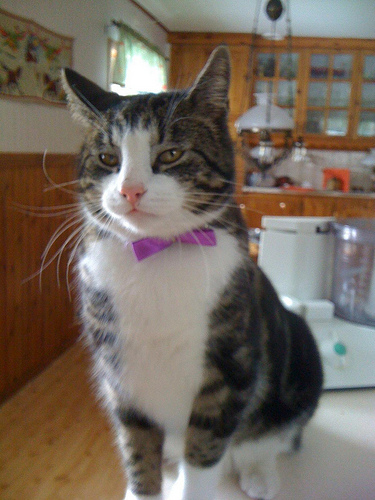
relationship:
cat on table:
[18, 43, 325, 499] [2, 143, 260, 498]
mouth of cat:
[105, 205, 164, 224] [29, 54, 362, 494]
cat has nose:
[18, 43, 325, 499] [116, 183, 147, 203]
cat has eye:
[18, 43, 325, 499] [155, 141, 190, 171]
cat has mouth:
[18, 43, 325, 499] [118, 200, 161, 220]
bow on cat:
[131, 227, 218, 264] [18, 43, 325, 499]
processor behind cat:
[256, 204, 357, 343] [18, 43, 325, 499]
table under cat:
[5, 322, 126, 499] [57, 43, 327, 498]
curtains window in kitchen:
[104, 18, 171, 94] [0, 0, 373, 499]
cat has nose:
[57, 43, 327, 498] [121, 185, 147, 205]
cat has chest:
[18, 43, 325, 499] [83, 234, 239, 425]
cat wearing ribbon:
[18, 43, 325, 499] [125, 225, 218, 261]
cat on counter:
[18, 43, 325, 499] [121, 386, 373, 498]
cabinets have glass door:
[243, 30, 372, 150] [253, 46, 299, 133]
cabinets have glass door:
[243, 30, 372, 150] [297, 48, 356, 141]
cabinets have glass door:
[243, 30, 372, 150] [354, 55, 373, 138]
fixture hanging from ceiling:
[224, 101, 310, 181] [128, 0, 374, 33]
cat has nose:
[18, 43, 325, 499] [118, 185, 145, 208]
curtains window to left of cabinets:
[104, 18, 171, 94] [167, 30, 373, 229]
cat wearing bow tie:
[57, 43, 327, 498] [129, 225, 216, 260]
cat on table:
[57, 43, 327, 498] [120, 390, 374, 498]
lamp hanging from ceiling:
[232, 0, 303, 176] [143, 1, 374, 40]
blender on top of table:
[254, 215, 372, 391] [310, 385, 373, 498]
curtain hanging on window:
[110, 21, 170, 93] [108, 40, 158, 89]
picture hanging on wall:
[0, 7, 75, 107] [2, 0, 170, 409]